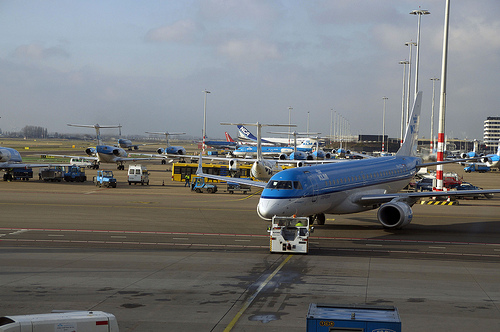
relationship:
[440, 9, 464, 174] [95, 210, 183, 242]
light pole on runway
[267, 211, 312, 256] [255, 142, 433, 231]
vehicle services plane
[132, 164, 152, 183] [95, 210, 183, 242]
van on runway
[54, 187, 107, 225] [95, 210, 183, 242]
lines on runway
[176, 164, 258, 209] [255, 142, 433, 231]
bus by plane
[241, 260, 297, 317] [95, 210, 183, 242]
oil on runway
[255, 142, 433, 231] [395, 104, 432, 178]
plane has tail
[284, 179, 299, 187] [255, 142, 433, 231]
windshield on plane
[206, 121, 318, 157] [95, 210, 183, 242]
planes on runway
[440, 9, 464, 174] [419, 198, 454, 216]
light pole has base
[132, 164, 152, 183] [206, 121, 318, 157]
van by planes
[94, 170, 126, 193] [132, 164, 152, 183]
car by van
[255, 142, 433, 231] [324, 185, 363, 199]
plane has stripe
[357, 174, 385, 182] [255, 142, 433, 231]
windows on plane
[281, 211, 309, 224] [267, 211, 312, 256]
people in vehicle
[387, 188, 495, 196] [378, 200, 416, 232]
wings have engines